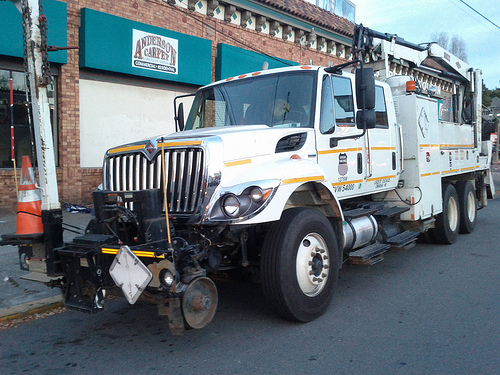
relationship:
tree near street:
[434, 30, 473, 64] [0, 172, 497, 372]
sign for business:
[131, 25, 180, 77] [12, 2, 400, 215]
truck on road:
[91, 47, 489, 323] [0, 157, 496, 374]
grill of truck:
[102, 145, 204, 224] [91, 47, 489, 323]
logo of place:
[131, 25, 180, 77] [12, 2, 400, 215]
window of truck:
[317, 71, 358, 131] [91, 47, 489, 323]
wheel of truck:
[264, 207, 338, 324] [91, 47, 489, 323]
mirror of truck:
[352, 59, 376, 125] [91, 47, 489, 323]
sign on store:
[131, 25, 180, 77] [12, 2, 400, 215]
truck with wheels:
[91, 47, 489, 323] [169, 276, 220, 329]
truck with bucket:
[91, 47, 489, 323] [389, 73, 418, 101]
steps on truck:
[373, 205, 425, 254] [91, 47, 489, 323]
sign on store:
[131, 25, 180, 77] [3, 3, 431, 242]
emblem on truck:
[335, 154, 352, 175] [91, 47, 489, 323]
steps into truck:
[373, 205, 425, 254] [91, 47, 489, 323]